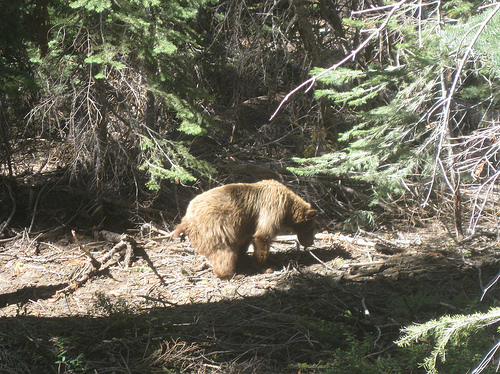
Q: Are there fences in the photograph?
A: No, there are no fences.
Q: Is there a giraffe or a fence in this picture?
A: No, there are no fences or giraffes.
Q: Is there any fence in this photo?
A: No, there are no fences.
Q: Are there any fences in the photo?
A: No, there are no fences.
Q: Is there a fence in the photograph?
A: No, there are no fences.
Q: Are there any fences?
A: No, there are no fences.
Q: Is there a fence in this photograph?
A: No, there are no fences.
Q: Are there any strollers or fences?
A: No, there are no fences or strollers.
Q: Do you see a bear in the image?
A: Yes, there is a bear.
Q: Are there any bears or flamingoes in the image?
A: Yes, there is a bear.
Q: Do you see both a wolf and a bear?
A: No, there is a bear but no wolves.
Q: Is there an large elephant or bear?
A: Yes, there is a large bear.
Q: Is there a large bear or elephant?
A: Yes, there is a large bear.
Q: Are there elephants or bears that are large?
A: Yes, the bear is large.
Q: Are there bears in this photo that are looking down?
A: Yes, there is a bear that is looking down.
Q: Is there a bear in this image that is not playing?
A: Yes, there is a bear that is looking down.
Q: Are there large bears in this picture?
A: Yes, there is a large bear.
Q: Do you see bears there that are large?
A: Yes, there is a bear that is large.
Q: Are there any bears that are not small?
A: Yes, there is a large bear.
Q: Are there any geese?
A: No, there are no geese.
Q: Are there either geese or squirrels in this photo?
A: No, there are no geese or squirrels.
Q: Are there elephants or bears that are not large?
A: No, there is a bear but it is large.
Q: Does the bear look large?
A: Yes, the bear is large.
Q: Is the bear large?
A: Yes, the bear is large.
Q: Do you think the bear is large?
A: Yes, the bear is large.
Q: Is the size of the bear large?
A: Yes, the bear is large.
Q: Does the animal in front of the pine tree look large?
A: Yes, the bear is large.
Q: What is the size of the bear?
A: The bear is large.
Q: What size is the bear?
A: The bear is large.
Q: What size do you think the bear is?
A: The bear is large.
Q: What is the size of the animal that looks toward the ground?
A: The bear is large.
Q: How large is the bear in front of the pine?
A: The bear is large.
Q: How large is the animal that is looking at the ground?
A: The bear is large.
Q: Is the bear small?
A: No, the bear is large.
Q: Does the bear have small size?
A: No, the bear is large.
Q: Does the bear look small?
A: No, the bear is large.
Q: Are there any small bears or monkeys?
A: No, there is a bear but it is large.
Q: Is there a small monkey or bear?
A: No, there is a bear but it is large.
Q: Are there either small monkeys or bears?
A: No, there is a bear but it is large.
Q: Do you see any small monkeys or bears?
A: No, there is a bear but it is large.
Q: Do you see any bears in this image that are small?
A: No, there is a bear but it is large.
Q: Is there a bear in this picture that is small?
A: No, there is a bear but it is large.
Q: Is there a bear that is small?
A: No, there is a bear but it is large.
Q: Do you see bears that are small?
A: No, there is a bear but it is large.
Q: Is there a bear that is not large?
A: No, there is a bear but it is large.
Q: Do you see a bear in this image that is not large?
A: No, there is a bear but it is large.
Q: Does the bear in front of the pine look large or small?
A: The bear is large.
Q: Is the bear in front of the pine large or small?
A: The bear is large.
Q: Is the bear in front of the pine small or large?
A: The bear is large.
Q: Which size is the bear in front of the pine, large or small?
A: The bear is large.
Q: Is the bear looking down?
A: Yes, the bear is looking down.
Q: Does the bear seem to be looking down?
A: Yes, the bear is looking down.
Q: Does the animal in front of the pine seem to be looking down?
A: Yes, the bear is looking down.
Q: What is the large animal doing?
A: The bear is looking down.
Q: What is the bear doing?
A: The bear is looking down.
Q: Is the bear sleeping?
A: No, the bear is looking down.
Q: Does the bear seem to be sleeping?
A: No, the bear is looking down.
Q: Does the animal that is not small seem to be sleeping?
A: No, the bear is looking down.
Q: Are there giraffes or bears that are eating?
A: No, there is a bear but it is looking down.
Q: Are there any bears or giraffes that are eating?
A: No, there is a bear but it is looking down.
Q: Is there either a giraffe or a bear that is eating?
A: No, there is a bear but it is looking down.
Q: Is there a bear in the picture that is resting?
A: No, there is a bear but it is looking down.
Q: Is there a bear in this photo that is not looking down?
A: No, there is a bear but it is looking down.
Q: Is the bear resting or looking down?
A: The bear is looking down.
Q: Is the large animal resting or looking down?
A: The bear is looking down.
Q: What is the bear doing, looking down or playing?
A: The bear is looking down.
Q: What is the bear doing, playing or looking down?
A: The bear is looking down.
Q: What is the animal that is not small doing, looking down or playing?
A: The bear is looking down.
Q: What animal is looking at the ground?
A: The bear is looking at the ground.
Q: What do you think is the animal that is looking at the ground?
A: The animal is a bear.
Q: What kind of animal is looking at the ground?
A: The animal is a bear.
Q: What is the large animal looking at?
A: The bear is looking at the ground.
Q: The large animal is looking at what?
A: The bear is looking at the ground.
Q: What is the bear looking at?
A: The bear is looking at the ground.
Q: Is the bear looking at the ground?
A: Yes, the bear is looking at the ground.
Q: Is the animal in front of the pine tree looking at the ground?
A: Yes, the bear is looking at the ground.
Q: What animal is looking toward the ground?
A: The bear is looking toward the ground.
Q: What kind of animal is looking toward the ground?
A: The animal is a bear.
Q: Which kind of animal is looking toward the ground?
A: The animal is a bear.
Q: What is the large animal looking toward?
A: The bear is looking toward the ground.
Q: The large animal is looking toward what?
A: The bear is looking toward the ground.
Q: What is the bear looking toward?
A: The bear is looking toward the ground.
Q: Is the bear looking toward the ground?
A: Yes, the bear is looking toward the ground.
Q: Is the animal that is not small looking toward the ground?
A: Yes, the bear is looking toward the ground.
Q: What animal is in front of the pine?
A: The bear is in front of the pine.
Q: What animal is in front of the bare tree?
A: The bear is in front of the pine.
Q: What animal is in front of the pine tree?
A: The bear is in front of the pine.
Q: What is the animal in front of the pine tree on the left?
A: The animal is a bear.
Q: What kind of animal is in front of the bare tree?
A: The animal is a bear.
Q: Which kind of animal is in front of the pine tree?
A: The animal is a bear.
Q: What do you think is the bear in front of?
A: The bear is in front of the pine.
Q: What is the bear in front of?
A: The bear is in front of the pine.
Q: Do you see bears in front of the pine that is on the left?
A: Yes, there is a bear in front of the pine tree.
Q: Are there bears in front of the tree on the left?
A: Yes, there is a bear in front of the pine tree.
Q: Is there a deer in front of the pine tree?
A: No, there is a bear in front of the pine tree.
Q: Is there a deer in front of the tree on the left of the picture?
A: No, there is a bear in front of the pine tree.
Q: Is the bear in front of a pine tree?
A: Yes, the bear is in front of a pine tree.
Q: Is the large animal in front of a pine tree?
A: Yes, the bear is in front of a pine tree.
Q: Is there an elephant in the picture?
A: No, there are no elephants.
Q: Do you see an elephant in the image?
A: No, there are no elephants.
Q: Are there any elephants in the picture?
A: No, there are no elephants.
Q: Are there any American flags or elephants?
A: No, there are no elephants or American flags.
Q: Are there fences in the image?
A: No, there are no fences.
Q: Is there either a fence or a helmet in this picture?
A: No, there are no fences or helmets.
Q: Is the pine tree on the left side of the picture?
A: Yes, the pine tree is on the left of the image.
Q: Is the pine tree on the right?
A: No, the pine tree is on the left of the image.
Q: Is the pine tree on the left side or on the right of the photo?
A: The pine tree is on the left of the image.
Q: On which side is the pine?
A: The pine is on the left of the image.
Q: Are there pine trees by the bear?
A: Yes, there is a pine tree by the bear.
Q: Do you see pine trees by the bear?
A: Yes, there is a pine tree by the bear.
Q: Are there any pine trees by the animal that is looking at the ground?
A: Yes, there is a pine tree by the bear.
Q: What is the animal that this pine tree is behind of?
A: The animal is a bear.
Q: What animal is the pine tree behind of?
A: The pine tree is behind the bear.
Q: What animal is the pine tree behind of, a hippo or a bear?
A: The pine tree is behind a bear.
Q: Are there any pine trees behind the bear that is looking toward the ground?
A: Yes, there is a pine tree behind the bear.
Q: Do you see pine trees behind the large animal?
A: Yes, there is a pine tree behind the bear.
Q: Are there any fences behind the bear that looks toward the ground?
A: No, there is a pine tree behind the bear.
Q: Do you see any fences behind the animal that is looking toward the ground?
A: No, there is a pine tree behind the bear.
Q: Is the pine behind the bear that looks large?
A: Yes, the pine is behind the bear.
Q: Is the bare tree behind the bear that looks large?
A: Yes, the pine is behind the bear.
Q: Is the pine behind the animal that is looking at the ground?
A: Yes, the pine is behind the bear.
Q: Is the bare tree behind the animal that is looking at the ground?
A: Yes, the pine is behind the bear.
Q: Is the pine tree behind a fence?
A: No, the pine tree is behind the bear.